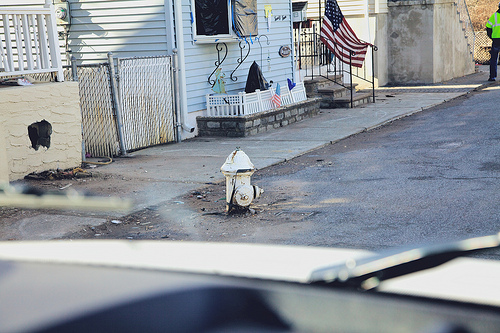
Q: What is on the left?
A: House.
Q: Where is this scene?
A: Small town.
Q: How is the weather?
A: Fair.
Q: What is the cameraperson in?
A: Car.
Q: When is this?
A: Daytime.